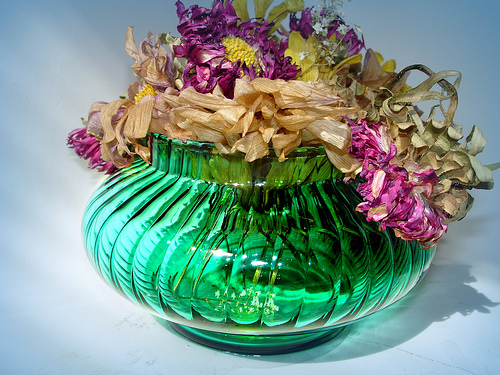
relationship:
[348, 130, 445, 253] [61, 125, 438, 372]
purple flower in vase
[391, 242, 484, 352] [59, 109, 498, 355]
shadow of pot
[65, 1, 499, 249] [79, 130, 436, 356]
flowers in pot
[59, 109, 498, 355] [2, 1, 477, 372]
pot placed on floor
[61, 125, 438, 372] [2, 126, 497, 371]
vase on surface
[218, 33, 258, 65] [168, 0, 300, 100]
flower on flower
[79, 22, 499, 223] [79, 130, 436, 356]
leaves protrude from pot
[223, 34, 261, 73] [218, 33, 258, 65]
yellow bits on flower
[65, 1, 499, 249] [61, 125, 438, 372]
flowers in vase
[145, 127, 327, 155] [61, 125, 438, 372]
rim on vase